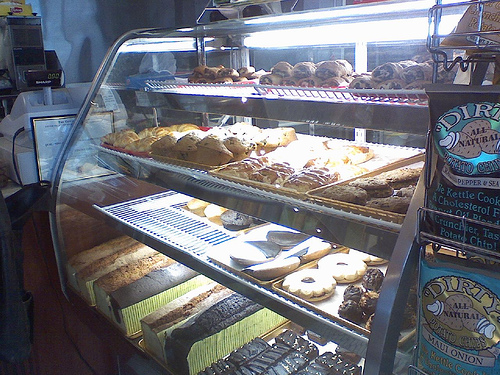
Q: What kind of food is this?
A: Pastries.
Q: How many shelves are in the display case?
A: Four.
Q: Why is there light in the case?
A: Light bulb inside case.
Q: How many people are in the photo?
A: None.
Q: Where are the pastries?
A: Inside glass display case.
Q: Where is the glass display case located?
A: Store.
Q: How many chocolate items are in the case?
A: Five.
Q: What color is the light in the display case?
A: White.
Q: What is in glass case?
A: Pastries.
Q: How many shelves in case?
A: 4.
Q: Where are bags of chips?
A: Right side.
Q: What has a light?
A: Display case.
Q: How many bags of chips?
A: Two.